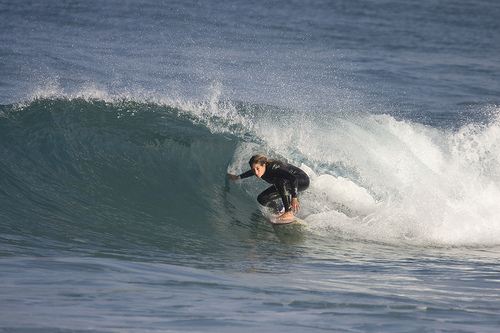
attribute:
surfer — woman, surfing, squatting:
[224, 152, 310, 218]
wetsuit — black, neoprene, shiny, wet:
[244, 163, 301, 209]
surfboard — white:
[264, 208, 308, 226]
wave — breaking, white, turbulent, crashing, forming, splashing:
[0, 89, 498, 247]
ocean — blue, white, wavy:
[1, 0, 499, 333]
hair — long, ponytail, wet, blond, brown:
[247, 155, 283, 163]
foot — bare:
[275, 213, 295, 222]